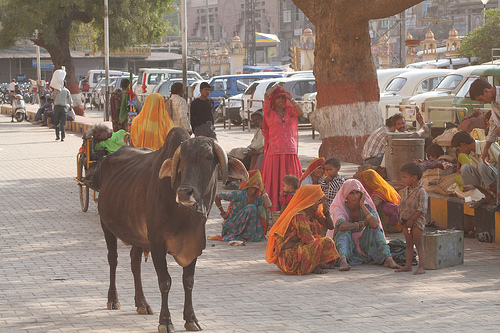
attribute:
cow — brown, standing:
[23, 90, 232, 329]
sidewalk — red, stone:
[230, 285, 380, 330]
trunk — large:
[312, 5, 382, 149]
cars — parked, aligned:
[110, 55, 495, 167]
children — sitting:
[237, 146, 489, 276]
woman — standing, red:
[264, 87, 299, 195]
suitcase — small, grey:
[416, 226, 479, 281]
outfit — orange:
[267, 176, 351, 292]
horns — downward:
[165, 129, 237, 190]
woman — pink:
[323, 189, 409, 273]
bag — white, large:
[52, 60, 64, 92]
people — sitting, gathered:
[191, 61, 484, 257]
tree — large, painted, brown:
[295, 5, 427, 181]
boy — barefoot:
[397, 154, 424, 267]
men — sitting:
[345, 112, 495, 208]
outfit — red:
[258, 95, 297, 211]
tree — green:
[0, 9, 191, 106]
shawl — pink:
[265, 93, 298, 129]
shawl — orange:
[253, 182, 328, 260]